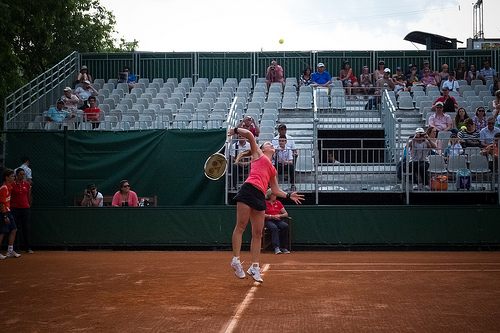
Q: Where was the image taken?
A: It was taken at the stadium.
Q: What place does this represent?
A: It represents the stadium.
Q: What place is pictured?
A: It is a stadium.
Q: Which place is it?
A: It is a stadium.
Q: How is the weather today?
A: It is clear.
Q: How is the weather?
A: It is clear.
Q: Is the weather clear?
A: Yes, it is clear.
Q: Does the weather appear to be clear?
A: Yes, it is clear.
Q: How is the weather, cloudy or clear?
A: It is clear.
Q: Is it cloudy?
A: No, it is clear.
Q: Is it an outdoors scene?
A: Yes, it is outdoors.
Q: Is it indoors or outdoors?
A: It is outdoors.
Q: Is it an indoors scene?
A: No, it is outdoors.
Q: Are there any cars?
A: No, there are no cars.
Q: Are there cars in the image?
A: No, there are no cars.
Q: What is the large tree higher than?
A: The tree is higher than the stadium.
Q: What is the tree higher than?
A: The tree is higher than the stadium.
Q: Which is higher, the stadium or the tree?
A: The tree is higher than the stadium.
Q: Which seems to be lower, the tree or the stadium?
A: The stadium is lower than the tree.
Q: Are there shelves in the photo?
A: No, there are no shelves.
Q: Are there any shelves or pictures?
A: No, there are no shelves or pictures.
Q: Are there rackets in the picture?
A: Yes, there is a racket.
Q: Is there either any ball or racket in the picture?
A: Yes, there is a racket.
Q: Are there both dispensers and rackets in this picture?
A: No, there is a racket but no dispensers.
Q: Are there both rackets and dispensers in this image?
A: No, there is a racket but no dispensers.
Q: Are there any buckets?
A: No, there are no buckets.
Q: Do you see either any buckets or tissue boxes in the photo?
A: No, there are no buckets or tissue boxes.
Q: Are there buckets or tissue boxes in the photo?
A: No, there are no buckets or tissue boxes.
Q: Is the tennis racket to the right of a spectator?
A: No, the tennis racket is to the left of a spectator.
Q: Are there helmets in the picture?
A: No, there are no helmets.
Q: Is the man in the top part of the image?
A: Yes, the man is in the top of the image.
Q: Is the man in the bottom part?
A: No, the man is in the top of the image.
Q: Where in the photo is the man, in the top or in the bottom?
A: The man is in the top of the image.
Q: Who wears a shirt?
A: The man wears a shirt.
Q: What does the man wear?
A: The man wears a shirt.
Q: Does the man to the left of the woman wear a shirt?
A: Yes, the man wears a shirt.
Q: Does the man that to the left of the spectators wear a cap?
A: No, the man wears a shirt.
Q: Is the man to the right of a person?
A: Yes, the man is to the right of a person.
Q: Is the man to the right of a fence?
A: No, the man is to the right of a person.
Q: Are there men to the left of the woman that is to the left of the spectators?
A: Yes, there is a man to the left of the woman.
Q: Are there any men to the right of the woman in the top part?
A: No, the man is to the left of the woman.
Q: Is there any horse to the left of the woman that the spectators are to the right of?
A: No, there is a man to the left of the woman.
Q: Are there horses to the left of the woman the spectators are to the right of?
A: No, there is a man to the left of the woman.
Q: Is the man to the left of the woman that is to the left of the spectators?
A: Yes, the man is to the left of the woman.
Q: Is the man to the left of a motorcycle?
A: No, the man is to the left of the woman.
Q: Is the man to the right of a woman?
A: No, the man is to the left of a woman.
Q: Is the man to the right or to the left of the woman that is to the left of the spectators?
A: The man is to the left of the woman.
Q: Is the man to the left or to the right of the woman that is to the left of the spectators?
A: The man is to the left of the woman.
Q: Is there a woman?
A: Yes, there is a woman.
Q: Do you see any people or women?
A: Yes, there is a woman.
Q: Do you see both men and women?
A: Yes, there are both a woman and a man.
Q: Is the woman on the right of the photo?
A: Yes, the woman is on the right of the image.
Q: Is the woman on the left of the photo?
A: No, the woman is on the right of the image.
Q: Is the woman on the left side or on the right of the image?
A: The woman is on the right of the image.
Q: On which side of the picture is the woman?
A: The woman is on the right of the image.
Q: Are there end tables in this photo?
A: No, there are no end tables.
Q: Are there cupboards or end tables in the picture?
A: No, there are no end tables or cupboards.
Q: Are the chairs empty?
A: Yes, the chairs are empty.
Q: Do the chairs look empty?
A: Yes, the chairs are empty.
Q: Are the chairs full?
A: No, the chairs are empty.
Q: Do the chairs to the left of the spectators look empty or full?
A: The chairs are empty.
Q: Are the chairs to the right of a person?
A: Yes, the chairs are to the right of a person.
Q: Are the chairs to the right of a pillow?
A: No, the chairs are to the right of a person.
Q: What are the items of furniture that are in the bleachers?
A: The pieces of furniture are chairs.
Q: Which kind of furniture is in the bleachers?
A: The pieces of furniture are chairs.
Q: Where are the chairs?
A: The chairs are in the bleachers.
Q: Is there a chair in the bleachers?
A: Yes, there are chairs in the bleachers.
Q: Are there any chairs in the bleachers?
A: Yes, there are chairs in the bleachers.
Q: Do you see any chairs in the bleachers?
A: Yes, there are chairs in the bleachers.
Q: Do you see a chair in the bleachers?
A: Yes, there are chairs in the bleachers.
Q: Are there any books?
A: No, there are no books.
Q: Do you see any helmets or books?
A: No, there are no books or helmets.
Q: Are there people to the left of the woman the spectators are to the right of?
A: Yes, there is a person to the left of the woman.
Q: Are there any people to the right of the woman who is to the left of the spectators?
A: No, the person is to the left of the woman.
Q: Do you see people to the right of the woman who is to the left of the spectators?
A: No, the person is to the left of the woman.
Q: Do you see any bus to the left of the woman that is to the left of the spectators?
A: No, there is a person to the left of the woman.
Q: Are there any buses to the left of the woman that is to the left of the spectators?
A: No, there is a person to the left of the woman.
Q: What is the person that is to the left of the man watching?
A: The person is watching the match.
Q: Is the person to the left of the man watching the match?
A: Yes, the person is watching the match.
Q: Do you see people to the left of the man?
A: Yes, there is a person to the left of the man.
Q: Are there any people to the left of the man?
A: Yes, there is a person to the left of the man.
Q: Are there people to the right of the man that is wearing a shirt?
A: No, the person is to the left of the man.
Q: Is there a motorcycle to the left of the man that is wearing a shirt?
A: No, there is a person to the left of the man.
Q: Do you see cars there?
A: No, there are no cars.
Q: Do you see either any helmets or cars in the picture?
A: No, there are no cars or helmets.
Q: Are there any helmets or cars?
A: No, there are no cars or helmets.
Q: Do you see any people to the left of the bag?
A: Yes, there is a person to the left of the bag.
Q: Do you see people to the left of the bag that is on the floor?
A: Yes, there is a person to the left of the bag.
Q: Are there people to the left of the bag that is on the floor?
A: Yes, there is a person to the left of the bag.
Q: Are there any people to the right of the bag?
A: No, the person is to the left of the bag.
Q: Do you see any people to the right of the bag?
A: No, the person is to the left of the bag.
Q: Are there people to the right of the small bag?
A: No, the person is to the left of the bag.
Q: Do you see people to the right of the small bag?
A: No, the person is to the left of the bag.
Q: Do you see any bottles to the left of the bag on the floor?
A: No, there is a person to the left of the bag.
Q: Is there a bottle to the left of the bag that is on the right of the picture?
A: No, there is a person to the left of the bag.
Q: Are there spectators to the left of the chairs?
A: Yes, there are spectators to the left of the chairs.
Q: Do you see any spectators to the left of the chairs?
A: Yes, there are spectators to the left of the chairs.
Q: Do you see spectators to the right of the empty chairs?
A: Yes, there are spectators to the right of the chairs.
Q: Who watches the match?
A: The spectators watch the match.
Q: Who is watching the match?
A: The spectators are watching the match.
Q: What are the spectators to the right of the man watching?
A: The spectators are watching the match.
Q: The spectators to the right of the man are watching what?
A: The spectators are watching the match.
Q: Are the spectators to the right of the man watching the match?
A: Yes, the spectators are watching the match.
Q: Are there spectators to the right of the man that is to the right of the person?
A: Yes, there are spectators to the right of the man.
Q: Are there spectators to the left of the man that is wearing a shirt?
A: No, the spectators are to the right of the man.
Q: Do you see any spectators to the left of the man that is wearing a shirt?
A: No, the spectators are to the right of the man.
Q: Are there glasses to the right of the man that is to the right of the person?
A: No, there are spectators to the right of the man.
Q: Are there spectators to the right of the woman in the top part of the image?
A: Yes, there are spectators to the right of the woman.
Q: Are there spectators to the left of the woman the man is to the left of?
A: No, the spectators are to the right of the woman.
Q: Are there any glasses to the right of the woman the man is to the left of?
A: No, there are spectators to the right of the woman.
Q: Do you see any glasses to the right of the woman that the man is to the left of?
A: No, there are spectators to the right of the woman.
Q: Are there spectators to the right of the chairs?
A: Yes, there are spectators to the right of the chairs.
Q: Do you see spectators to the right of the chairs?
A: Yes, there are spectators to the right of the chairs.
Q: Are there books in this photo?
A: No, there are no books.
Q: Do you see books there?
A: No, there are no books.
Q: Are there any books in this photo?
A: No, there are no books.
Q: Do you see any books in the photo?
A: No, there are no books.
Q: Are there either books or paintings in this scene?
A: No, there are no books or paintings.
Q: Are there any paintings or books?
A: No, there are no books or paintings.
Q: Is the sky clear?
A: Yes, the sky is clear.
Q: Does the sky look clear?
A: Yes, the sky is clear.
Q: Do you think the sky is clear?
A: Yes, the sky is clear.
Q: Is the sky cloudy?
A: No, the sky is clear.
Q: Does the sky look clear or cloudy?
A: The sky is clear.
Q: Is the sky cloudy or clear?
A: The sky is clear.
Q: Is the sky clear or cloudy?
A: The sky is clear.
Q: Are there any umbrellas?
A: Yes, there is an umbrella.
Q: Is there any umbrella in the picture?
A: Yes, there is an umbrella.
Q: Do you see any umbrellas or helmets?
A: Yes, there is an umbrella.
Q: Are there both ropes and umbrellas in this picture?
A: No, there is an umbrella but no ropes.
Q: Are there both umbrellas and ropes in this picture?
A: No, there is an umbrella but no ropes.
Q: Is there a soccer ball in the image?
A: No, there are no soccer balls.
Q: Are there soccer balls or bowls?
A: No, there are no soccer balls or bowls.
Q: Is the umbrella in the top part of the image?
A: Yes, the umbrella is in the top of the image.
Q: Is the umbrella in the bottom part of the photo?
A: No, the umbrella is in the top of the image.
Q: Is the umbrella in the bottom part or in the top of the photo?
A: The umbrella is in the top of the image.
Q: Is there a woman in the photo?
A: Yes, there is a woman.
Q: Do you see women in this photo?
A: Yes, there is a woman.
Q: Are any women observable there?
A: Yes, there is a woman.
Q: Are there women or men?
A: Yes, there is a woman.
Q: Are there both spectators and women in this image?
A: Yes, there are both a woman and spectators.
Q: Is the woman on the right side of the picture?
A: Yes, the woman is on the right of the image.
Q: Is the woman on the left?
A: No, the woman is on the right of the image.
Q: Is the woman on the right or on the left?
A: The woman is on the right of the image.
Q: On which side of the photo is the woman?
A: The woman is on the right of the image.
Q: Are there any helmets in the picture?
A: No, there are no helmets.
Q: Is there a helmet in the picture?
A: No, there are no helmets.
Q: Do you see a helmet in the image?
A: No, there are no helmets.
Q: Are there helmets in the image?
A: No, there are no helmets.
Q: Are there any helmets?
A: No, there are no helmets.